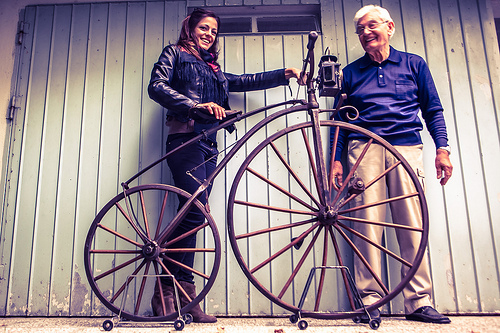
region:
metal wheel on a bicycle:
[80, 180, 222, 321]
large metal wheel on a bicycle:
[227, 118, 428, 322]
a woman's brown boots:
[150, 280, 217, 324]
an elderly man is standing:
[327, 5, 453, 327]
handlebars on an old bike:
[297, 28, 316, 103]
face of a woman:
[194, 15, 216, 47]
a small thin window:
[217, 11, 317, 33]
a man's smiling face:
[362, 35, 376, 45]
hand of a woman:
[202, 101, 227, 119]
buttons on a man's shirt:
[377, 63, 383, 81]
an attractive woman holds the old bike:
[144, 5, 304, 326]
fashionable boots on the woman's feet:
[146, 270, 223, 325]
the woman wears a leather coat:
[149, 42, 299, 134]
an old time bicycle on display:
[78, 30, 428, 331]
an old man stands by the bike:
[324, 4, 464, 331]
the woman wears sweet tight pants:
[157, 126, 219, 284]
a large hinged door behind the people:
[4, 3, 498, 313]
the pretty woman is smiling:
[173, 6, 221, 62]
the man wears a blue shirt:
[326, 48, 453, 161]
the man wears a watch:
[432, 140, 453, 153]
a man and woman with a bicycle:
[81, 7, 451, 331]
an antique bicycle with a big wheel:
[72, 33, 432, 330]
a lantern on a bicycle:
[295, 48, 344, 93]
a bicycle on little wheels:
[89, 267, 393, 332]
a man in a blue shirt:
[332, 41, 452, 146]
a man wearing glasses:
[351, 18, 393, 32]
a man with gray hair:
[349, 6, 398, 28]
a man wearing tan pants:
[338, 129, 445, 299]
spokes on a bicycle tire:
[237, 123, 429, 305]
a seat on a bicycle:
[191, 97, 250, 133]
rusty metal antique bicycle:
[81, 28, 432, 330]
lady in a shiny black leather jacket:
[145, 5, 307, 325]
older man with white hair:
[320, 5, 461, 332]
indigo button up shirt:
[322, 47, 454, 154]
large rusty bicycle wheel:
[221, 108, 434, 321]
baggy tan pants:
[345, 131, 435, 324]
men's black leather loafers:
[353, 303, 453, 329]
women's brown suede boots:
[147, 272, 220, 324]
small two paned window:
[172, 0, 329, 40]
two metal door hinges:
[7, 13, 27, 124]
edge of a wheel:
[256, 263, 263, 272]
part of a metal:
[338, 195, 400, 240]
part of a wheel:
[268, 175, 302, 222]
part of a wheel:
[284, 246, 318, 286]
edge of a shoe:
[428, 313, 443, 330]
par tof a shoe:
[425, 303, 430, 309]